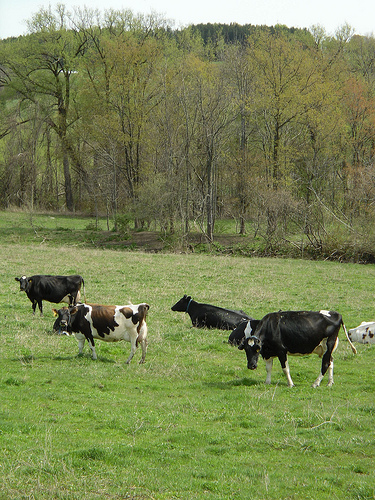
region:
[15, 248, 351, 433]
set of cows in field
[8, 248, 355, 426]
plenty of cows in field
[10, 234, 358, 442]
several cows in field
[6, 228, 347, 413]
multiple cows in field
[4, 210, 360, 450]
lots of cows in field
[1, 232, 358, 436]
group of cows in field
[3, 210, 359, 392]
variety of cows in field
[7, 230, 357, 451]
nice amount of cows in field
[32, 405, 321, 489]
patch of green grass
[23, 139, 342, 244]
set of thin trees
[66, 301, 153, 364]
cow standing in grass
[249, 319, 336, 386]
cow standing in grass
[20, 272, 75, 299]
cow standing in grass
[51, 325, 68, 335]
cow sitting in grass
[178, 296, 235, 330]
cow standing in grass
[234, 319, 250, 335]
cow standing in grass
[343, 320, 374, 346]
cow standing in grass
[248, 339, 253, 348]
white spot on cow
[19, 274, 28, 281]
white spot on cow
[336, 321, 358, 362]
white tail on cow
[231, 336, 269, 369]
white heart shape on a cows head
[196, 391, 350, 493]
green grass and sticks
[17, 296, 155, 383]
a brown and white cow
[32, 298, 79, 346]
a cow turned towards camera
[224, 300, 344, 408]
black and white cow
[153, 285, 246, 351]
black cow with blue collar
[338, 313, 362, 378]
white tail of a cow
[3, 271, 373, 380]
six cows in a field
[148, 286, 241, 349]
black cow laying down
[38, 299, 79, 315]
two brown cow ears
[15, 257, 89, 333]
Black cow in a field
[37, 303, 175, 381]
Black, white and brown cow in a field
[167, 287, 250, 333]
Black cow laying on a field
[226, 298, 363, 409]
Black and white cow in a field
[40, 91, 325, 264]
Trees by a field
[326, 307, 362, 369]
White tail on a cow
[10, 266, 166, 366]
Two cows in a field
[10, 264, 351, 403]
Five cows in a field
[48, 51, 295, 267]
Trees with green leaves on them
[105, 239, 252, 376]
Green and brown grass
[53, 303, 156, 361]
Black, brown and white cow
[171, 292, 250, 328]
black cow laying in the grass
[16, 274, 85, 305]
black cow standing in the field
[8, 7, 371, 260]
trees behind cows in a field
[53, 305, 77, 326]
face of cow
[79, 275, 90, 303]
tail of a black cow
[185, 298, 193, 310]
blue collar on a black cow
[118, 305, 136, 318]
small brown spot on a cow's back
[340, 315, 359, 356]
white tail of a black cow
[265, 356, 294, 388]
white legs of a black cow